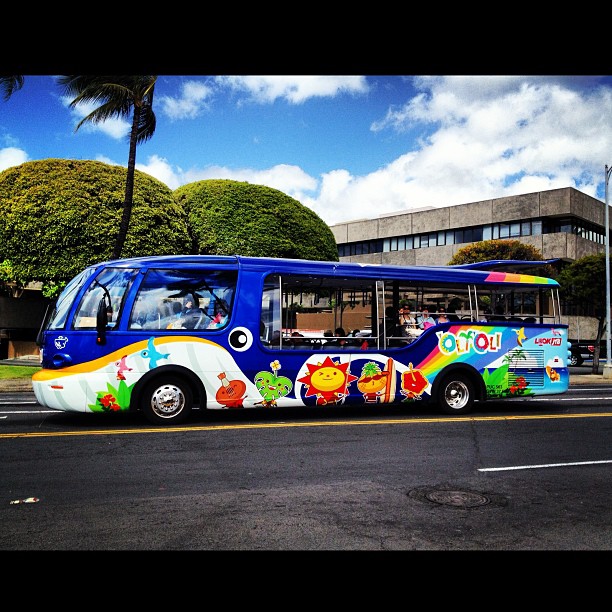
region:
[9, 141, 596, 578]
picture taken during the day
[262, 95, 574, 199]
the sky is full of white fluffy clouds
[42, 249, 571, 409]
the bus is full of people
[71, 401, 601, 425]
a yellow painted line on the road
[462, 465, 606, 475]
a white line painted on the road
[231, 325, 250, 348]
the bus has a eye on it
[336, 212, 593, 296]
the building is behind the bus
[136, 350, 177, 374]
symbol on the bus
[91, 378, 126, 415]
symbol on the bus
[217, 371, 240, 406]
symbol on the bus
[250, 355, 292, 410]
symbol on the bus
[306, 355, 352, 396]
symbol on the bus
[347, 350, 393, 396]
symbol on the bus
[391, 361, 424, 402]
symbol on the bus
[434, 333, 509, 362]
symbol on the bus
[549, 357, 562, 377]
symbol on the bus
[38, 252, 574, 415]
a bus painted like a whale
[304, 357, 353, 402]
painting of a sun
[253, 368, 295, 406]
painting of a green heart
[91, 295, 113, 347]
side view mirror on a bus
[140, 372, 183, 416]
front tire on a bus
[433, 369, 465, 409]
rear tire on a bus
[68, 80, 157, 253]
a tall palm tree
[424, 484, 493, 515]
a manhole cover on the street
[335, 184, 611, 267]
stone building with windows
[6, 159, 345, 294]
a couple trees with green leaves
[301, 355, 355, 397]
red and yellow sun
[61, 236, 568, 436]
the big colorful bus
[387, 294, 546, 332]
people sitting in the back of the bus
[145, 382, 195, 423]
the front bus wheel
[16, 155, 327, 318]
round trees behind the bus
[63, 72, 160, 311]
tall palm tree beside the bus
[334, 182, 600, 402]
the large grey building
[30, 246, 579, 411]
a bus with several pictures painted on it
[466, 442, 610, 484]
a white line painted on a street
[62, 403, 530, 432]
a yellow line painted on a street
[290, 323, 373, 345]
people sitting on a bus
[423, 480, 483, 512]
a metal man hole cover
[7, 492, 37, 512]
a plastic bottle on the road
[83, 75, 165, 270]
a tall palm tree next to a street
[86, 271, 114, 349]
a rear view mirror on a bus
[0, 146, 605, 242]
A cloudy sky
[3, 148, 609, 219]
The cloudy sky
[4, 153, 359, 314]
A set of well manicured trees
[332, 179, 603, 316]
The concrete building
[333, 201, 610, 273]
A concrete building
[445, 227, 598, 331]
The trees in front the building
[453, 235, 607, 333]
A set of trees in the building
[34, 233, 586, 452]
the blue passenger bus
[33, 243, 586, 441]
A blue passenger bus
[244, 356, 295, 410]
green heart on bus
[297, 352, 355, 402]
yellow and red sun on bus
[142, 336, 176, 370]
blue bird on front of bus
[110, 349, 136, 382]
red bird on front of bus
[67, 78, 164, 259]
palm tree behind bus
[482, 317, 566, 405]
beach scene on back of bus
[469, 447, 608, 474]
white line on road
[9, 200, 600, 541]
bus on the road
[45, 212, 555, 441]
the bus is blue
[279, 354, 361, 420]
sun decal on bus